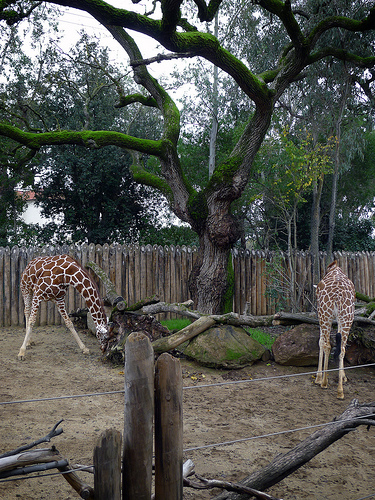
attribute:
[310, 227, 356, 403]
giraffe — down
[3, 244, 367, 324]
fence — wooden 